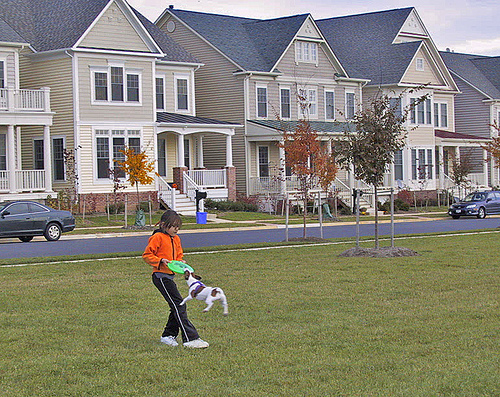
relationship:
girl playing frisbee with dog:
[144, 210, 210, 351] [178, 269, 230, 318]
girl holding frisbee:
[144, 210, 210, 351] [165, 258, 194, 279]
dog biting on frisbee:
[178, 269, 230, 318] [165, 258, 194, 279]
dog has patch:
[178, 269, 230, 318] [186, 283, 206, 299]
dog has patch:
[178, 269, 230, 318] [210, 286, 221, 298]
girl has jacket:
[144, 210, 210, 351] [143, 231, 186, 281]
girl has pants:
[144, 210, 210, 351] [152, 273, 200, 342]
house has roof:
[2, 2, 239, 220] [1, 1, 198, 68]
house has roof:
[152, 7, 376, 217] [155, 4, 367, 86]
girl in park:
[144, 210, 210, 351] [3, 216, 500, 393]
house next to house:
[2, 2, 239, 220] [152, 7, 376, 217]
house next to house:
[152, 7, 376, 217] [304, 7, 492, 217]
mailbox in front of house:
[192, 189, 208, 225] [2, 2, 239, 220]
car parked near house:
[0, 199, 74, 247] [2, 2, 239, 220]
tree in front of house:
[124, 142, 155, 230] [2, 2, 239, 220]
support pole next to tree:
[351, 188, 365, 258] [331, 80, 421, 254]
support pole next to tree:
[387, 185, 400, 252] [331, 80, 421, 254]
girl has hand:
[144, 210, 210, 351] [159, 258, 173, 268]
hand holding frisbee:
[180, 258, 188, 266] [165, 258, 194, 279]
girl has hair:
[144, 210, 210, 351] [158, 208, 182, 234]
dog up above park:
[178, 269, 230, 318] [3, 216, 500, 393]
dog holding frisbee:
[178, 269, 230, 318] [165, 258, 194, 279]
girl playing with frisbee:
[144, 210, 210, 351] [165, 258, 194, 279]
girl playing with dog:
[144, 210, 210, 351] [178, 269, 230, 318]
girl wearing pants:
[144, 210, 210, 351] [152, 273, 200, 342]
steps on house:
[158, 189, 198, 217] [2, 2, 239, 220]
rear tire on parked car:
[46, 224, 60, 241] [0, 199, 74, 247]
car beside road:
[0, 199, 74, 247] [1, 210, 499, 268]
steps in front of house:
[158, 189, 198, 217] [2, 2, 239, 220]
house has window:
[2, 2, 239, 220] [91, 68, 112, 104]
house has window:
[2, 2, 239, 220] [110, 63, 127, 103]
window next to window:
[94, 135, 114, 181] [112, 134, 128, 181]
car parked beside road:
[0, 199, 74, 247] [1, 210, 499, 268]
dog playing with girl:
[178, 269, 230, 318] [144, 210, 210, 351]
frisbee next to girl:
[165, 258, 194, 279] [144, 210, 210, 351]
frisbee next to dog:
[165, 258, 194, 279] [178, 269, 230, 318]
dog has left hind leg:
[178, 269, 230, 318] [202, 298, 217, 314]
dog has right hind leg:
[178, 269, 230, 318] [222, 298, 230, 315]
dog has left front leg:
[178, 269, 230, 318] [178, 292, 192, 306]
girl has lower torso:
[144, 210, 210, 351] [150, 258, 177, 271]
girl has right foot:
[144, 210, 210, 351] [183, 336, 208, 353]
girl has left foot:
[144, 210, 210, 351] [161, 333, 180, 348]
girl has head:
[144, 210, 210, 351] [156, 209, 183, 236]